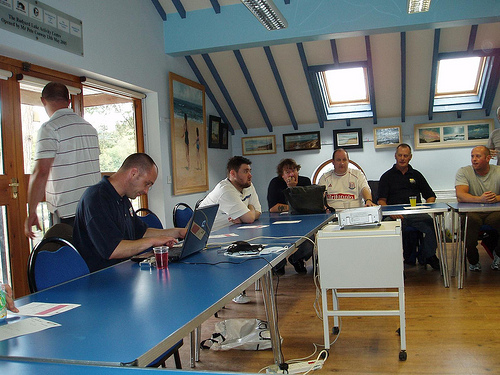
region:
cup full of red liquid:
[130, 228, 176, 284]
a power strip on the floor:
[259, 337, 333, 372]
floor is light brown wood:
[412, 299, 499, 367]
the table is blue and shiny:
[49, 264, 196, 352]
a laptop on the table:
[130, 193, 257, 288]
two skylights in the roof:
[269, 26, 489, 144]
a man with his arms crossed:
[185, 140, 284, 260]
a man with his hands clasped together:
[451, 110, 496, 245]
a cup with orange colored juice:
[395, 185, 444, 224]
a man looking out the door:
[10, 77, 102, 274]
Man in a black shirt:
[374, 140, 436, 202]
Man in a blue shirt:
[72, 152, 160, 262]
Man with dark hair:
[194, 153, 264, 222]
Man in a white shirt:
[200, 153, 262, 219]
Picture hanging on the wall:
[280, 130, 323, 152]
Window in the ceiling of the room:
[311, 64, 376, 117]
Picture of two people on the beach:
[164, 68, 212, 198]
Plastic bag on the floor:
[200, 317, 282, 355]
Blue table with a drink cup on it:
[8, 242, 270, 354]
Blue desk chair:
[25, 234, 97, 294]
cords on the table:
[206, 226, 338, 366]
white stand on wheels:
[315, 217, 427, 351]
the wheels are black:
[307, 316, 434, 373]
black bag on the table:
[279, 178, 335, 213]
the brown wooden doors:
[6, 70, 100, 300]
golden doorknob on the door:
[7, 173, 41, 215]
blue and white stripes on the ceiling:
[203, 38, 365, 150]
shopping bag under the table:
[196, 313, 342, 372]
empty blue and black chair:
[12, 230, 112, 310]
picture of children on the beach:
[145, 55, 251, 248]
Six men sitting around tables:
[76, 140, 498, 255]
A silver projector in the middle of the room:
[335, 200, 385, 230]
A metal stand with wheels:
[317, 225, 406, 363]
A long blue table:
[0, 210, 342, 366]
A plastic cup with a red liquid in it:
[152, 244, 171, 270]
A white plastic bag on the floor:
[212, 318, 287, 353]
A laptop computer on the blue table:
[130, 201, 222, 263]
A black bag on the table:
[283, 181, 334, 216]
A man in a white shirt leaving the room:
[24, 78, 109, 228]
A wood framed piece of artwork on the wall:
[166, 69, 210, 194]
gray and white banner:
[0, 1, 117, 67]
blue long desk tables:
[92, 272, 216, 374]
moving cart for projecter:
[312, 225, 424, 370]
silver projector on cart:
[333, 203, 390, 241]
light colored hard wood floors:
[456, 318, 480, 369]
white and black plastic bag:
[205, 308, 265, 374]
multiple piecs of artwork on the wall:
[226, 126, 498, 163]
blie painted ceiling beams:
[196, 60, 483, 109]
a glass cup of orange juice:
[398, 187, 437, 222]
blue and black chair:
[35, 211, 89, 320]